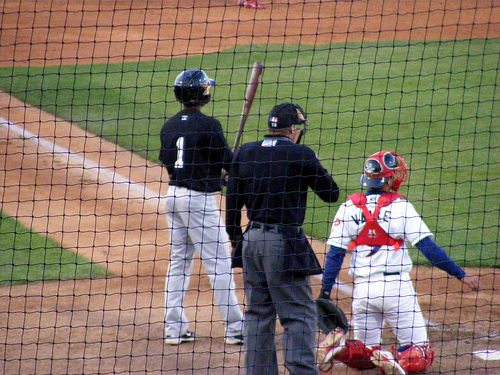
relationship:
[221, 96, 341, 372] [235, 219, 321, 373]
man wearing pants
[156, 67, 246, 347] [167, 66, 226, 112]
batter wears helmet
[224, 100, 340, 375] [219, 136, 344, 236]
man wears shirt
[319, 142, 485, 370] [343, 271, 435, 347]
catcher wears pants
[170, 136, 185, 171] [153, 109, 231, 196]
number on shirt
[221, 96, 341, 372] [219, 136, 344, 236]
man has shirt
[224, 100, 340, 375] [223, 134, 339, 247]
man wears shirt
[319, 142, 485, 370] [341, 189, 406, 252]
catcher wears red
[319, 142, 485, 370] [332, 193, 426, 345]
catcher wears white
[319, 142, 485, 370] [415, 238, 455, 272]
catcher wears blue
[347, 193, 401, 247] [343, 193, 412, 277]
shape across back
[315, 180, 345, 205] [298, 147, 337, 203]
elbow in sleeve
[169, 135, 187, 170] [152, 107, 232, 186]
digit on shirt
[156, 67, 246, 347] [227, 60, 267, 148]
batter holding bat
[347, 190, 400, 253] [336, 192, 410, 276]
straps across back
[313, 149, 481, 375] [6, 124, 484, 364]
catcher in dirt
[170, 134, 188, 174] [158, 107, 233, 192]
number on shirt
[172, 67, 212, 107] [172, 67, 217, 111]
helmet on head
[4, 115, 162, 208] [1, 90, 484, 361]
line in dirt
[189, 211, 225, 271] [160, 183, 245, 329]
wrinkles on pants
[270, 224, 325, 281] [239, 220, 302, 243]
pouch hanging from hip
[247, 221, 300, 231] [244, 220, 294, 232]
belt through loops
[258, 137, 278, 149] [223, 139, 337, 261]
logo on shirt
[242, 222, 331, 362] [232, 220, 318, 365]
pair of pants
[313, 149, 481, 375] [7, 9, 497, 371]
catcher on dirt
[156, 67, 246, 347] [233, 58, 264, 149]
batter holding bat